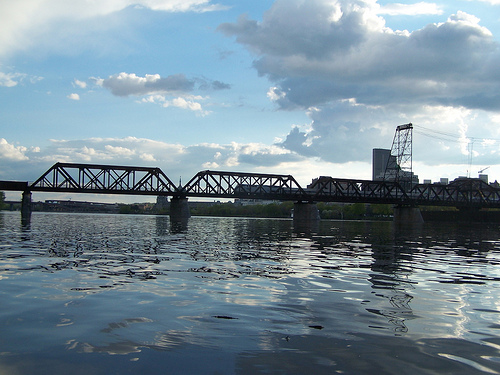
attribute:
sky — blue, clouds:
[171, 37, 230, 68]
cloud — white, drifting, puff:
[302, 38, 390, 115]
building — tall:
[369, 97, 434, 195]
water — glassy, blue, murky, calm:
[145, 223, 391, 339]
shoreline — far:
[62, 211, 371, 291]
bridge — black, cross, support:
[1, 121, 374, 214]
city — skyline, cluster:
[349, 95, 440, 197]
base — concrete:
[154, 205, 212, 226]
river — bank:
[197, 275, 440, 373]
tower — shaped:
[368, 99, 436, 199]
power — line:
[413, 130, 478, 159]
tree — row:
[314, 190, 420, 221]